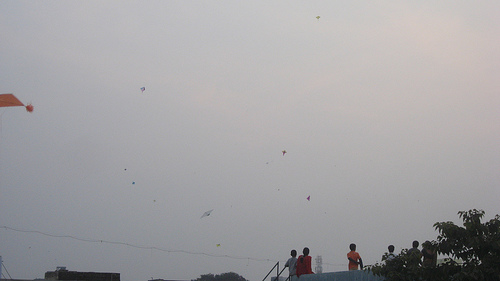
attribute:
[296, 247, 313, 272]
dress — orange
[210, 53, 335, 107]
cloud — cloudy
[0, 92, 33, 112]
kite — orange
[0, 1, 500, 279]
sky — blue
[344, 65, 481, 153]
clouds — white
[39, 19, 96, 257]
sky — blue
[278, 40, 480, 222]
clouds — white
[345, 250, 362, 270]
shirt — orange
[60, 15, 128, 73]
clouds — white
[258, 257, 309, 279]
rails — small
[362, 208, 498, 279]
tree — green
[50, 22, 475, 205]
sky — blue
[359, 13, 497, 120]
cloud — white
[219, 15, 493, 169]
clouds — white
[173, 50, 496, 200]
sky — blue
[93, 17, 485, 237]
sky — blue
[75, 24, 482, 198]
sky — grey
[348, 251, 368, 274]
shirt — orange